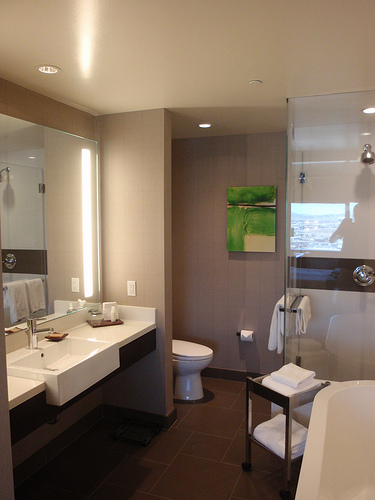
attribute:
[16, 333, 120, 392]
sink — bathroom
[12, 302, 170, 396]
counter — bathroom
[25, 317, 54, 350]
faucet — metal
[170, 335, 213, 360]
toilet seat — down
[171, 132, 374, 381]
wall — tiled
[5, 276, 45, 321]
towels — white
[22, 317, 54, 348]
water fixture — metal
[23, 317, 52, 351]
water faucet — silver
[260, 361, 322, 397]
towels — cotton, folded, white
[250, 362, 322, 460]
towels — folded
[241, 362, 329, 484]
rack — wooden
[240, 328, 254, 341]
toilet paper — rolled